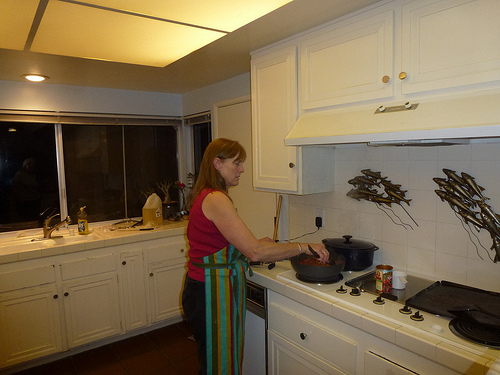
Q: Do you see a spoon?
A: No, there are no spoons.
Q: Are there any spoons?
A: No, there are no spoons.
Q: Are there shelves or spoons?
A: No, there are no spoons or shelves.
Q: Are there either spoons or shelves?
A: No, there are no spoons or shelves.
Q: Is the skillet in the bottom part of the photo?
A: Yes, the skillet is in the bottom of the image.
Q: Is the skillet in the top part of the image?
A: No, the skillet is in the bottom of the image.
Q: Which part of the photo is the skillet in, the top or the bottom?
A: The skillet is in the bottom of the image.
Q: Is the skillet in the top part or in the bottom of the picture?
A: The skillet is in the bottom of the image.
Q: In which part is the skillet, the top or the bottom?
A: The skillet is in the bottom of the image.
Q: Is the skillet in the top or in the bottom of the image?
A: The skillet is in the bottom of the image.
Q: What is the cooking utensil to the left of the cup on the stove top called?
A: The cooking utensil is a skillet.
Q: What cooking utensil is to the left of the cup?
A: The cooking utensil is a skillet.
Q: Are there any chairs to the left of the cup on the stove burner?
A: No, there is a skillet to the left of the cup.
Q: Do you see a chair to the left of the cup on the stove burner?
A: No, there is a skillet to the left of the cup.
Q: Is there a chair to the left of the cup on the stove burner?
A: No, there is a skillet to the left of the cup.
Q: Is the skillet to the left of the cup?
A: Yes, the skillet is to the left of the cup.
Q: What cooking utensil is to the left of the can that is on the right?
A: The cooking utensil is a skillet.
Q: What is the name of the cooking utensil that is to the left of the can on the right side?
A: The cooking utensil is a skillet.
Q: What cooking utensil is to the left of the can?
A: The cooking utensil is a skillet.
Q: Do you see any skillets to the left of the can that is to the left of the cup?
A: Yes, there is a skillet to the left of the can.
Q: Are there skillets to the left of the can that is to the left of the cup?
A: Yes, there is a skillet to the left of the can.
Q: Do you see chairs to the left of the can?
A: No, there is a skillet to the left of the can.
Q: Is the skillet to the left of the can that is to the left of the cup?
A: Yes, the skillet is to the left of the can.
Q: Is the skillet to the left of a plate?
A: No, the skillet is to the left of the can.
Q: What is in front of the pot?
A: The skillet is in front of the pot.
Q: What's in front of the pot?
A: The skillet is in front of the pot.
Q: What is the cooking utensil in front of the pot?
A: The cooking utensil is a skillet.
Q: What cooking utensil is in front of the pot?
A: The cooking utensil is a skillet.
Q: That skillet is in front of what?
A: The skillet is in front of the pot.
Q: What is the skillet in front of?
A: The skillet is in front of the pot.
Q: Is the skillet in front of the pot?
A: Yes, the skillet is in front of the pot.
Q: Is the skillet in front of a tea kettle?
A: No, the skillet is in front of the pot.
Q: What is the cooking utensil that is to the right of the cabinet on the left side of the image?
A: The cooking utensil is a skillet.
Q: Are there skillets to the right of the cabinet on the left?
A: Yes, there is a skillet to the right of the cabinet.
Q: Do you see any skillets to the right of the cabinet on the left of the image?
A: Yes, there is a skillet to the right of the cabinet.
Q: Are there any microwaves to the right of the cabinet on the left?
A: No, there is a skillet to the right of the cabinet.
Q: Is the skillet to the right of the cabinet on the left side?
A: Yes, the skillet is to the right of the cabinet.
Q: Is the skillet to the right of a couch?
A: No, the skillet is to the right of the cabinet.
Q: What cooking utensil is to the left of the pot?
A: The cooking utensil is a skillet.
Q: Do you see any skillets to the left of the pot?
A: Yes, there is a skillet to the left of the pot.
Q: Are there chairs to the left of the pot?
A: No, there is a skillet to the left of the pot.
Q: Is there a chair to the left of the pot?
A: No, there is a skillet to the left of the pot.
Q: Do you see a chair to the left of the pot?
A: No, there is a skillet to the left of the pot.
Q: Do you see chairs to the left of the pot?
A: No, there is a skillet to the left of the pot.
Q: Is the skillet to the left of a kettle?
A: No, the skillet is to the left of the pot.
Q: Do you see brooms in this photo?
A: No, there are no brooms.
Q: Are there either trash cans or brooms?
A: No, there are no brooms or trash cans.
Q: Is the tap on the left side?
A: Yes, the tap is on the left of the image.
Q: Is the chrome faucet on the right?
A: No, the tap is on the left of the image.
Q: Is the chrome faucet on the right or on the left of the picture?
A: The tap is on the left of the image.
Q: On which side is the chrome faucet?
A: The tap is on the left of the image.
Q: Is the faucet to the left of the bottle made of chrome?
A: Yes, the faucet is made of chrome.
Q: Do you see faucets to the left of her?
A: Yes, there is a faucet to the left of the woman.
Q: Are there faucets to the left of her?
A: Yes, there is a faucet to the left of the woman.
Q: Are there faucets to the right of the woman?
A: No, the faucet is to the left of the woman.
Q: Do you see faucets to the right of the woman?
A: No, the faucet is to the left of the woman.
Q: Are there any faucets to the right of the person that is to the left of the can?
A: No, the faucet is to the left of the woman.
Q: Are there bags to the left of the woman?
A: No, there is a faucet to the left of the woman.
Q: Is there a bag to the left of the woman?
A: No, there is a faucet to the left of the woman.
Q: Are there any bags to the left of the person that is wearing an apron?
A: No, there is a faucet to the left of the woman.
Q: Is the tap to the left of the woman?
A: Yes, the tap is to the left of the woman.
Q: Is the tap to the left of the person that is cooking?
A: Yes, the tap is to the left of the woman.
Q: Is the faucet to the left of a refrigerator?
A: No, the faucet is to the left of the woman.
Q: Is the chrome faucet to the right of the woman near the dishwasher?
A: No, the faucet is to the left of the woman.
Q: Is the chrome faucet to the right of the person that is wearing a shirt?
A: No, the faucet is to the left of the woman.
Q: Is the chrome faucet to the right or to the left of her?
A: The faucet is to the left of the woman.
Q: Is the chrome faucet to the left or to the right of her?
A: The faucet is to the left of the woman.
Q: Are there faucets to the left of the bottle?
A: Yes, there is a faucet to the left of the bottle.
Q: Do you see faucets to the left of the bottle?
A: Yes, there is a faucet to the left of the bottle.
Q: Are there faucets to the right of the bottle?
A: No, the faucet is to the left of the bottle.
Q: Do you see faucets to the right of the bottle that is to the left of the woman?
A: No, the faucet is to the left of the bottle.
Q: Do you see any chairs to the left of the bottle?
A: No, there is a faucet to the left of the bottle.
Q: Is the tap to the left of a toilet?
A: No, the tap is to the left of the bottle.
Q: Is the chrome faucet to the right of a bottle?
A: No, the tap is to the left of a bottle.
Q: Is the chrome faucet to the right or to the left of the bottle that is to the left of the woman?
A: The tap is to the left of the bottle.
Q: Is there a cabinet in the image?
A: Yes, there is a cabinet.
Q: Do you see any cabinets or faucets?
A: Yes, there is a cabinet.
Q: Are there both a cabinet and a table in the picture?
A: No, there is a cabinet but no tables.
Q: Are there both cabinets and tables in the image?
A: No, there is a cabinet but no tables.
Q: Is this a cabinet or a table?
A: This is a cabinet.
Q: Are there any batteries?
A: No, there are no batteries.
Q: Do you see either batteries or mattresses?
A: No, there are no batteries or mattresses.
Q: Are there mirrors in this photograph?
A: No, there are no mirrors.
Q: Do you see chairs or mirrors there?
A: No, there are no mirrors or chairs.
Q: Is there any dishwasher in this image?
A: Yes, there is a dishwasher.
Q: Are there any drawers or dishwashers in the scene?
A: Yes, there is a dishwasher.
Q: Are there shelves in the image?
A: No, there are no shelves.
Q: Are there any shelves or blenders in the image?
A: No, there are no shelves or blenders.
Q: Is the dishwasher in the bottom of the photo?
A: Yes, the dishwasher is in the bottom of the image.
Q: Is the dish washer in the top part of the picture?
A: No, the dish washer is in the bottom of the image.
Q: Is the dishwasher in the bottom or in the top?
A: The dishwasher is in the bottom of the image.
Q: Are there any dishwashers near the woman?
A: Yes, there is a dishwasher near the woman.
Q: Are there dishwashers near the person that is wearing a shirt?
A: Yes, there is a dishwasher near the woman.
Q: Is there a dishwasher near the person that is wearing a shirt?
A: Yes, there is a dishwasher near the woman.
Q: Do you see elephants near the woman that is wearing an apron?
A: No, there is a dishwasher near the woman.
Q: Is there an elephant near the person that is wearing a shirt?
A: No, there is a dishwasher near the woman.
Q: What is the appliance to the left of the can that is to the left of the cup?
A: The appliance is a dishwasher.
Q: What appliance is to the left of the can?
A: The appliance is a dishwasher.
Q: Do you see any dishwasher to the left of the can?
A: Yes, there is a dishwasher to the left of the can.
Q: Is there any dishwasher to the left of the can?
A: Yes, there is a dishwasher to the left of the can.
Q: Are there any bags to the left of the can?
A: No, there is a dishwasher to the left of the can.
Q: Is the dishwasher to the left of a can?
A: Yes, the dishwasher is to the left of a can.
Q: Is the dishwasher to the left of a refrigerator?
A: No, the dishwasher is to the left of a can.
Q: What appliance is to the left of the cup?
A: The appliance is a dishwasher.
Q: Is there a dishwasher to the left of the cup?
A: Yes, there is a dishwasher to the left of the cup.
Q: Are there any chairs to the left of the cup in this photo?
A: No, there is a dishwasher to the left of the cup.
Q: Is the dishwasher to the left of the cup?
A: Yes, the dishwasher is to the left of the cup.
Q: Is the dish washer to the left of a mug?
A: No, the dish washer is to the left of the cup.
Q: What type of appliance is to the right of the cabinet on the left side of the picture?
A: The appliance is a dishwasher.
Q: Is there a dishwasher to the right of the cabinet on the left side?
A: Yes, there is a dishwasher to the right of the cabinet.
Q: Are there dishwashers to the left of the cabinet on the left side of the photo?
A: No, the dishwasher is to the right of the cabinet.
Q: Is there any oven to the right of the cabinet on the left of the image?
A: No, there is a dishwasher to the right of the cabinet.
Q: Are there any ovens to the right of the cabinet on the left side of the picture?
A: No, there is a dishwasher to the right of the cabinet.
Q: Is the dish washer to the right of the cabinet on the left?
A: Yes, the dish washer is to the right of the cabinet.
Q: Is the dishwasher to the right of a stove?
A: No, the dishwasher is to the right of the cabinet.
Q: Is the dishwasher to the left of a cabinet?
A: No, the dishwasher is to the right of a cabinet.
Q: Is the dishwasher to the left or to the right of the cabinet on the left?
A: The dishwasher is to the right of the cabinet.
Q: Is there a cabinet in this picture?
A: Yes, there is a cabinet.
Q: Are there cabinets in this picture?
A: Yes, there is a cabinet.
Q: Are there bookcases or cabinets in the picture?
A: Yes, there is a cabinet.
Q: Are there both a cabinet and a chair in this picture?
A: No, there is a cabinet but no chairs.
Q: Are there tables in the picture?
A: No, there are no tables.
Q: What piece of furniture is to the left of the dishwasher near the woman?
A: The piece of furniture is a cabinet.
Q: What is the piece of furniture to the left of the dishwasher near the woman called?
A: The piece of furniture is a cabinet.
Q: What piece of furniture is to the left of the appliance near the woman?
A: The piece of furniture is a cabinet.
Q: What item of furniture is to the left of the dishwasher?
A: The piece of furniture is a cabinet.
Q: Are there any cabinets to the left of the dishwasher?
A: Yes, there is a cabinet to the left of the dishwasher.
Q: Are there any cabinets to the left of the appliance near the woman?
A: Yes, there is a cabinet to the left of the dishwasher.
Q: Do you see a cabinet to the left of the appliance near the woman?
A: Yes, there is a cabinet to the left of the dishwasher.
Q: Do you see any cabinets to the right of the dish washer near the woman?
A: No, the cabinet is to the left of the dish washer.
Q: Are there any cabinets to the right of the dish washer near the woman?
A: No, the cabinet is to the left of the dish washer.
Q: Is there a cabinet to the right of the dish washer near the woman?
A: No, the cabinet is to the left of the dish washer.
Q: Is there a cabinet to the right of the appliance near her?
A: No, the cabinet is to the left of the dish washer.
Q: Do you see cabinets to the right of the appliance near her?
A: No, the cabinet is to the left of the dish washer.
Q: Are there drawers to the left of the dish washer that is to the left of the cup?
A: No, there is a cabinet to the left of the dish washer.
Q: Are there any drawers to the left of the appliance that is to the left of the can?
A: No, there is a cabinet to the left of the dish washer.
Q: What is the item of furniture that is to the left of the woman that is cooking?
A: The piece of furniture is a cabinet.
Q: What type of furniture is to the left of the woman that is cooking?
A: The piece of furniture is a cabinet.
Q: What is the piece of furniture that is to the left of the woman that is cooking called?
A: The piece of furniture is a cabinet.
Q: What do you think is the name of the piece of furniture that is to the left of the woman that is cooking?
A: The piece of furniture is a cabinet.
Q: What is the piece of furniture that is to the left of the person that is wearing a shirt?
A: The piece of furniture is a cabinet.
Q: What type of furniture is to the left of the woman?
A: The piece of furniture is a cabinet.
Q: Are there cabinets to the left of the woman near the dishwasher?
A: Yes, there is a cabinet to the left of the woman.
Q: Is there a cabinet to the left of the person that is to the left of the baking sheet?
A: Yes, there is a cabinet to the left of the woman.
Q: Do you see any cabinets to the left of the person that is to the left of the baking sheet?
A: Yes, there is a cabinet to the left of the woman.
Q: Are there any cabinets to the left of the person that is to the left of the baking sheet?
A: Yes, there is a cabinet to the left of the woman.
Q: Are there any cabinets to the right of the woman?
A: No, the cabinet is to the left of the woman.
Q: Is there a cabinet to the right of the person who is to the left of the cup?
A: No, the cabinet is to the left of the woman.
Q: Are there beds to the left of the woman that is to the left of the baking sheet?
A: No, there is a cabinet to the left of the woman.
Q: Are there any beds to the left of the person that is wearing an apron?
A: No, there is a cabinet to the left of the woman.